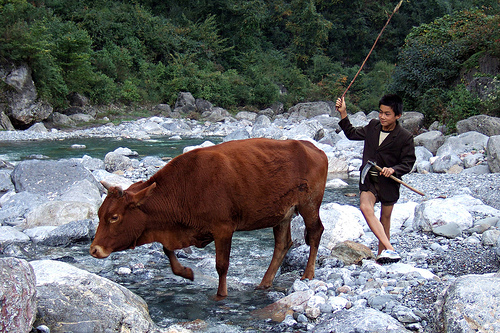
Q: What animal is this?
A: Cow.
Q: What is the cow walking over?
A: Water and rocks.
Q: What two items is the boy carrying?
A: Pick ax and stick.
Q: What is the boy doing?
A: Getting cow to cross stream.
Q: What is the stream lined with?
A: Rocks.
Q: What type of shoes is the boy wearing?
A: Sneakers.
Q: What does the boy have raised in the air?
A: Long stick.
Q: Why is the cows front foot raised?
A: To take a step.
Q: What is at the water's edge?
A: Lush trees.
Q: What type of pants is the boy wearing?
A: Black shorts.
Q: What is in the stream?
A: Rocks.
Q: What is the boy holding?
A: Stick.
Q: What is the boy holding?
A: Stick.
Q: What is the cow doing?
A: Crossing water.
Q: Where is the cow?
A: In the water.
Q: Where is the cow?
A: Crossing the water.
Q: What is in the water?
A: Rocks.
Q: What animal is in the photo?
A: Cow.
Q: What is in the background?
A: Trees.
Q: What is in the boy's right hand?
A: Stick.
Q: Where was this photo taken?
A: Mountains.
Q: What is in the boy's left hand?
A: Scythe.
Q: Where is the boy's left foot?
A: On the rock.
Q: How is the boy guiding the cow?
A: A stick.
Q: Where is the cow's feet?
A: In the water.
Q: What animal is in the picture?
A: A cow.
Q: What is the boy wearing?
A: A blazer.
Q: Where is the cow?
A: In front of the boy?.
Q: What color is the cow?
A: Brown.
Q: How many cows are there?
A: One.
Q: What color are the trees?
A: Green.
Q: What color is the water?
A: Blue.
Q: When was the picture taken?
A: Daytime.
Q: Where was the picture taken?
A: In a rocky riverbed.